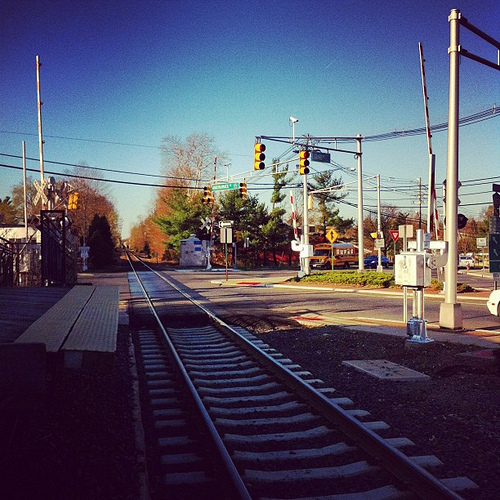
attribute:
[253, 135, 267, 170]
trafficsignal — electric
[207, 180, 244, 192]
sign — green, white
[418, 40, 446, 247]
crossing arm — red, white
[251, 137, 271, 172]
trafficlight — yellow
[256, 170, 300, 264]
tree — large, green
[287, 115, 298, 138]
trafficcamera — security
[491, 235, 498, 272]
street sign — several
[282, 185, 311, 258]
crossing arm — red, white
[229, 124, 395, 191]
light — red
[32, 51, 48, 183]
pole — red, white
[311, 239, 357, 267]
bus — small, yellow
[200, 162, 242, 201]
sign — red, white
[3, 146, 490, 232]
power line — long, electrical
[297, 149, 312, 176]
traffic signal — electric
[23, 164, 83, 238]
sign — railroad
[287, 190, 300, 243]
arm — red, white, striped